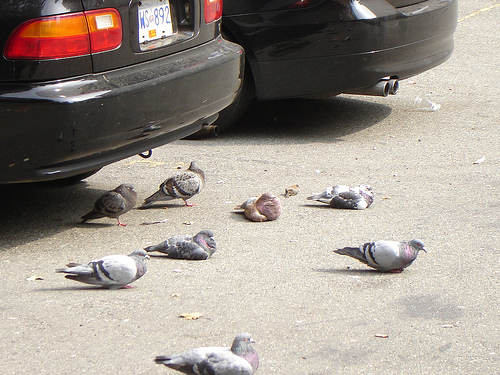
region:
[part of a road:
[246, 216, 305, 285]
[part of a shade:
[318, 237, 390, 339]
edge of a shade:
[280, 132, 330, 170]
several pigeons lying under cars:
[0, 0, 453, 365]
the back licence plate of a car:
[107, 0, 192, 40]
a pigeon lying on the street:
[335, 226, 435, 291]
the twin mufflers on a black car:
[341, 67, 414, 119]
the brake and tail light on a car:
[1, 5, 141, 76]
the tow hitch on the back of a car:
[132, 138, 161, 164]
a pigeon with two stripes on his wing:
[50, 241, 165, 321]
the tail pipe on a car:
[189, 113, 224, 146]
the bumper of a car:
[11, 42, 283, 177]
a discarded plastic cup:
[408, 85, 448, 122]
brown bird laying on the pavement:
[239, 186, 286, 230]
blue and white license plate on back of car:
[134, 1, 185, 46]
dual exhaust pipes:
[357, 64, 405, 111]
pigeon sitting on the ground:
[324, 224, 439, 279]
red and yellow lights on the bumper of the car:
[14, 10, 123, 67]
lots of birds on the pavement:
[74, 169, 267, 367]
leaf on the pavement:
[176, 308, 216, 325]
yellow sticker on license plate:
[146, 26, 160, 43]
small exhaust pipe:
[194, 116, 224, 138]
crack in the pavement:
[459, 1, 494, 25]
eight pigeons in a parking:
[79, 154, 428, 368]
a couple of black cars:
[3, 4, 454, 174]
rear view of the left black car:
[1, 4, 232, 169]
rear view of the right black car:
[304, 0, 474, 94]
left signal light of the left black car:
[15, 6, 131, 72]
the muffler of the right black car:
[321, 58, 414, 117]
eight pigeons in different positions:
[94, 180, 463, 372]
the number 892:
[150, 5, 177, 32]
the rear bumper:
[24, 41, 243, 176]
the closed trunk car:
[81, 1, 225, 67]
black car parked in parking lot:
[0, 0, 251, 255]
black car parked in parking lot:
[140, 0, 470, 150]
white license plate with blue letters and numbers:
[130, 0, 170, 45]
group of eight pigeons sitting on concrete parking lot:
[50, 150, 435, 370]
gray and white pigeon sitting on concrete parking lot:
[325, 230, 425, 275]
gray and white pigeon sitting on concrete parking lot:
[305, 175, 380, 210]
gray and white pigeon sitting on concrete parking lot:
[140, 325, 265, 365]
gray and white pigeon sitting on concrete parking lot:
[51, 241, 156, 286]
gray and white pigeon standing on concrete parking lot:
[138, 155, 213, 214]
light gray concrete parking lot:
[1, 0, 498, 374]